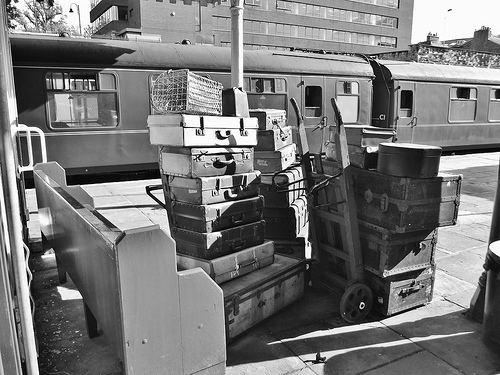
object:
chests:
[352, 162, 463, 236]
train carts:
[268, 96, 378, 326]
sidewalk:
[18, 147, 500, 374]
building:
[85, 0, 419, 61]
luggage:
[145, 111, 259, 148]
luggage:
[157, 143, 255, 179]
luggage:
[165, 169, 263, 205]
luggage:
[169, 193, 267, 235]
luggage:
[174, 238, 276, 285]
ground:
[25, 148, 500, 374]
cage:
[146, 67, 225, 115]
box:
[375, 141, 443, 181]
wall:
[395, 0, 415, 53]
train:
[7, 29, 499, 177]